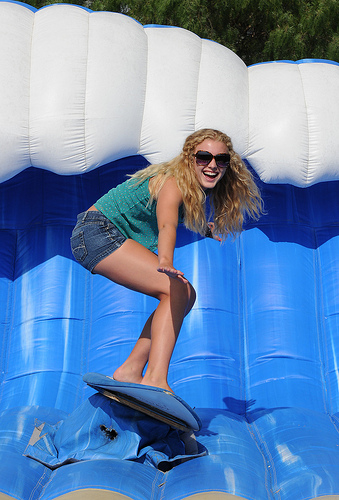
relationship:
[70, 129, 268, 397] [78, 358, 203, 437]
girl balancing on surfboard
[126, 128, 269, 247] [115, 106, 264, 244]
blonde hair of woman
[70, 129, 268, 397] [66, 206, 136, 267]
girl wearing shorts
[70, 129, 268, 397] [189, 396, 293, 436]
girl has shadow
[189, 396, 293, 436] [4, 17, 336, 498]
shadow on pad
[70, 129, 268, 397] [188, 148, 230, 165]
girl wearing sunglasses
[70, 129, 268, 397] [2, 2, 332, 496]
girl in front of inflatable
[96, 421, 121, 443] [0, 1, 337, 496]
rip in tarp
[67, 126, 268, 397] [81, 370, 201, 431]
girl on surfboard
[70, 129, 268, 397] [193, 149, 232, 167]
girl wearing sunglasses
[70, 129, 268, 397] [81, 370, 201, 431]
girl crouched on surfboard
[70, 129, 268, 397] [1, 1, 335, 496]
girl surfing on inflatable waves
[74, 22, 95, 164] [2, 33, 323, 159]
seam in material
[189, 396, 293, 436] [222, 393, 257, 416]
shadow looks like bird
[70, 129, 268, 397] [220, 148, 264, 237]
girl with hair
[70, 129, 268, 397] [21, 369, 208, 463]
girl riding simulator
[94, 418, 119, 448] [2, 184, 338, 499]
tear in covering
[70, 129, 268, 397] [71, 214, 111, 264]
girl wearing shorts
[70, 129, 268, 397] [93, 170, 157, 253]
girl wearing tank top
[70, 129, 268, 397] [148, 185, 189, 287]
girl balancing with arm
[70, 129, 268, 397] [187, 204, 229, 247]
girl balancing with arm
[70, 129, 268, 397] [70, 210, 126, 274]
girl has shorts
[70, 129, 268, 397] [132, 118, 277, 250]
girl has hair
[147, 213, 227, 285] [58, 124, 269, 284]
hands of woman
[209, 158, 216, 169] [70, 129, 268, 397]
nose of girl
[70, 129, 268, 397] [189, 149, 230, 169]
girl wearing sunglasses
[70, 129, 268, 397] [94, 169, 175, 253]
girl wearing shirt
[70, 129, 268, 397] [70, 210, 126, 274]
girl wearing shorts